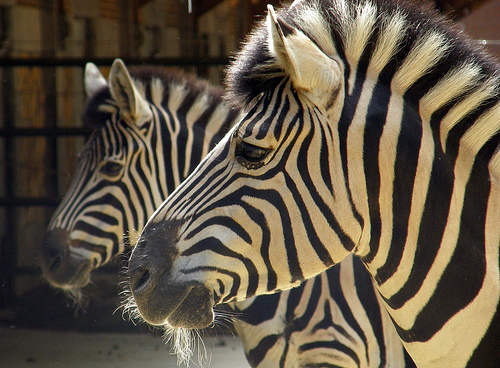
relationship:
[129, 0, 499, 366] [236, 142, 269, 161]
zebra has eye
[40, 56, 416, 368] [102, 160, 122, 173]
zebra has eye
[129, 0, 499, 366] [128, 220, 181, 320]
zebra has nose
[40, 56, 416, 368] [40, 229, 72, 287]
zebra has nose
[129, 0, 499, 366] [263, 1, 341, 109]
zebra has ear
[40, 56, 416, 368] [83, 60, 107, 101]
zebra has ear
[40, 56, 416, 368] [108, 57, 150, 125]
zebra has ear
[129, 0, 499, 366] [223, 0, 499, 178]
zebra has mane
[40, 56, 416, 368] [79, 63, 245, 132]
zebra has mane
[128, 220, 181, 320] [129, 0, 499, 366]
nose of zebra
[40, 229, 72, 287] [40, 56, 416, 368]
nose of zebra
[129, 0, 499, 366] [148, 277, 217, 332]
zebra has mouth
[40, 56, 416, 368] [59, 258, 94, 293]
zebra has mouth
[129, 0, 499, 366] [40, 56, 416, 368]
zebra next to zebra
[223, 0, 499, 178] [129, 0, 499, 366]
mane on zebra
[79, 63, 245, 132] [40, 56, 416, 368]
mane on zebra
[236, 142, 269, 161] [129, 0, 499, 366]
eye of zebra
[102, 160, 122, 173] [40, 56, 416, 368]
eye of zebra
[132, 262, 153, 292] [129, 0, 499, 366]
nostril of zebra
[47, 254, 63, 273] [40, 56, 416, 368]
nostril of zebra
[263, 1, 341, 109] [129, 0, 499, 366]
ear of zebra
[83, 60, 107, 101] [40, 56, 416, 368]
ear of zebra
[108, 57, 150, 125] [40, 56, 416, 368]
ear of zebra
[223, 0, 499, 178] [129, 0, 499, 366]
mane of zebra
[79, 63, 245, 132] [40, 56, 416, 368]
mane of zebra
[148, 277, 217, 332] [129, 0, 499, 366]
mouth of zebra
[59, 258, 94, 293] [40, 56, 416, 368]
mouth of zebra